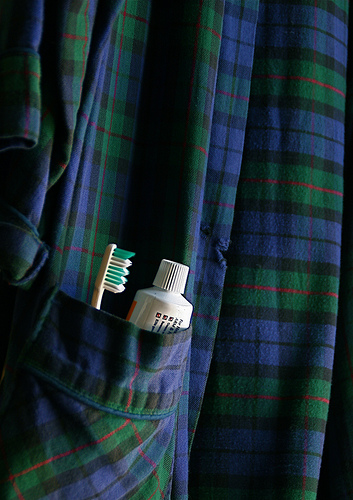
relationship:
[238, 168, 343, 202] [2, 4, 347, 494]
red line in robe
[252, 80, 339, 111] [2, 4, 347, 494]
green line in robe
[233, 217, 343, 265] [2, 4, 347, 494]
blue line in robe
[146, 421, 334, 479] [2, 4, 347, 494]
blue lines in robe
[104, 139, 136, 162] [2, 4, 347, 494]
green section in robe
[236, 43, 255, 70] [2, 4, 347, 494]
blue section in robe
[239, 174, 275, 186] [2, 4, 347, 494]
red section in robe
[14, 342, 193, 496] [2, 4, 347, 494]
plaid section in robe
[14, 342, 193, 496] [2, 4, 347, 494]
plaid section on robe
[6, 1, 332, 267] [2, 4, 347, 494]
plaid checkers are on robe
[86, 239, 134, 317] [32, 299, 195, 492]
toothbrush in pocket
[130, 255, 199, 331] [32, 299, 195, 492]
toothpaste in pocket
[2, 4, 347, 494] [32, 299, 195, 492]
robe has pocket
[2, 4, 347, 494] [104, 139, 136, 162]
robe has green section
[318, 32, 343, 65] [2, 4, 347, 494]
blue block on robe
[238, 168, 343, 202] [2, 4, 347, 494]
red line on robe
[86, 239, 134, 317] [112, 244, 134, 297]
toothbrush has bristles